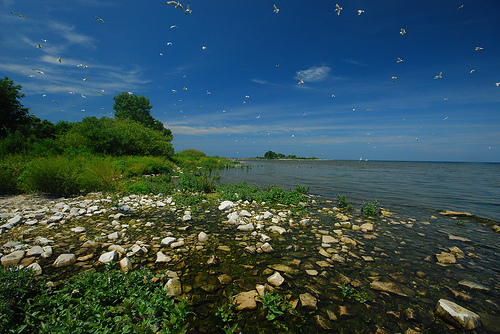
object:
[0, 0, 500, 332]
scenery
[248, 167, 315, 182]
water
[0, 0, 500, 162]
sky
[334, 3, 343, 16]
bird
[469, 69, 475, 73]
birds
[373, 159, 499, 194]
water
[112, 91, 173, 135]
tree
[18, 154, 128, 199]
bush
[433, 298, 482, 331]
rocks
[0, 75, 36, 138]
bushy tree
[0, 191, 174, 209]
land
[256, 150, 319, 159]
island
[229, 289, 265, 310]
plants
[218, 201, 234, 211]
plants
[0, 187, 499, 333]
plants and rocks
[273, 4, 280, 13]
bird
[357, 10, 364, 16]
bird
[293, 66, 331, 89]
cloud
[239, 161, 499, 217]
ocean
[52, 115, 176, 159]
trees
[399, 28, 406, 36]
bird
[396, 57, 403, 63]
bird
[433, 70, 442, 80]
bird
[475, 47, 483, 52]
bird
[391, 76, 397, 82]
bird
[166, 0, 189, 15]
bird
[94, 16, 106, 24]
bird